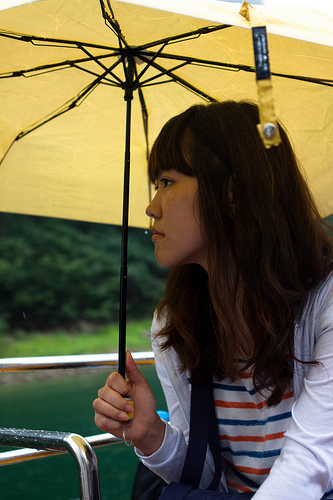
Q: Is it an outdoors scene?
A: Yes, it is outdoors.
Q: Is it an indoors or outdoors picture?
A: It is outdoors.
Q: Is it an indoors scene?
A: No, it is outdoors.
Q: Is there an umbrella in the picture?
A: Yes, there is an umbrella.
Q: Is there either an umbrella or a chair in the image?
A: Yes, there is an umbrella.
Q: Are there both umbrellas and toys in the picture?
A: No, there is an umbrella but no toys.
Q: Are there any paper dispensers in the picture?
A: No, there are no paper dispensers.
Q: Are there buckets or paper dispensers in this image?
A: No, there are no paper dispensers or buckets.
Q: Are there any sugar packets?
A: No, there are no sugar packets.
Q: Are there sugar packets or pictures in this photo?
A: No, there are no sugar packets or pictures.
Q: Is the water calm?
A: Yes, the water is calm.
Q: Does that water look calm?
A: Yes, the water is calm.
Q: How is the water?
A: The water is calm.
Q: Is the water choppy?
A: No, the water is calm.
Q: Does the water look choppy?
A: No, the water is calm.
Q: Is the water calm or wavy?
A: The water is calm.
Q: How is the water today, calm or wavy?
A: The water is calm.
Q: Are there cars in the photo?
A: No, there are no cars.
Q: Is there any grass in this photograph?
A: Yes, there is grass.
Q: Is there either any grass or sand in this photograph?
A: Yes, there is grass.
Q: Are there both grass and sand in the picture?
A: No, there is grass but no sand.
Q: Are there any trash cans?
A: No, there are no trash cans.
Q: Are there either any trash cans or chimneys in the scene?
A: No, there are no trash cans or chimneys.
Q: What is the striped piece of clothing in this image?
A: The clothing item is a shirt.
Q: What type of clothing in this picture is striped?
A: The clothing is a shirt.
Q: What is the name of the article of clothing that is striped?
A: The clothing item is a shirt.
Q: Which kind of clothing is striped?
A: The clothing is a shirt.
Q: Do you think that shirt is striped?
A: Yes, the shirt is striped.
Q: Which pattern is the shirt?
A: The shirt is striped.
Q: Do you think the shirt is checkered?
A: No, the shirt is striped.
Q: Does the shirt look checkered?
A: No, the shirt is striped.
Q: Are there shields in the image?
A: No, there are no shields.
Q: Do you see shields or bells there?
A: No, there are no shields or bells.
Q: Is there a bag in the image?
A: Yes, there is a bag.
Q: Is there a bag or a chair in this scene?
A: Yes, there is a bag.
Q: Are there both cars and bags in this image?
A: No, there is a bag but no cars.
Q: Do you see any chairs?
A: No, there are no chairs.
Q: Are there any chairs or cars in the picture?
A: No, there are no chairs or cars.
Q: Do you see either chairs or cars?
A: No, there are no chairs or cars.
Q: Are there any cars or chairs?
A: No, there are no chairs or cars.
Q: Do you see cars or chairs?
A: No, there are no chairs or cars.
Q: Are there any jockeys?
A: No, there are no jockeys.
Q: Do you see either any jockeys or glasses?
A: No, there are no jockeys or glasses.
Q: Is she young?
A: Yes, the girl is young.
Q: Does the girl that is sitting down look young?
A: Yes, the girl is young.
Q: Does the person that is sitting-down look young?
A: Yes, the girl is young.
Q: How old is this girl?
A: The girl is young.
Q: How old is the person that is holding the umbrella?
A: The girl is young.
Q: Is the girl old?
A: No, the girl is young.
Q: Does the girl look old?
A: No, the girl is young.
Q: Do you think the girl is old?
A: No, the girl is young.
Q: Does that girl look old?
A: No, the girl is young.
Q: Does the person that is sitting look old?
A: No, the girl is young.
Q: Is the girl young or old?
A: The girl is young.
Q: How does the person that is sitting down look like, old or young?
A: The girl is young.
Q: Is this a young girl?
A: Yes, this is a young girl.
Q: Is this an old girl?
A: No, this is a young girl.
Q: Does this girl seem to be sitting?
A: Yes, the girl is sitting.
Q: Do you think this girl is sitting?
A: Yes, the girl is sitting.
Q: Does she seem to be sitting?
A: Yes, the girl is sitting.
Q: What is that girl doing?
A: The girl is sitting.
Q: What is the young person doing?
A: The girl is sitting.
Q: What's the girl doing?
A: The girl is sitting.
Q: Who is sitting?
A: The girl is sitting.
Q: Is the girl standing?
A: No, the girl is sitting.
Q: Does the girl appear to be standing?
A: No, the girl is sitting.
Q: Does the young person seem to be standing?
A: No, the girl is sitting.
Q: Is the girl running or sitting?
A: The girl is sitting.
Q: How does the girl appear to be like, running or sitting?
A: The girl is sitting.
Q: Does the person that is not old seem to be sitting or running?
A: The girl is sitting.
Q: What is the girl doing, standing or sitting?
A: The girl is sitting.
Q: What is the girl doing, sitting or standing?
A: The girl is sitting.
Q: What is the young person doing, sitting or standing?
A: The girl is sitting.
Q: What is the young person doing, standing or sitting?
A: The girl is sitting.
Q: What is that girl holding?
A: The girl is holding the umbrella.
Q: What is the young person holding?
A: The girl is holding the umbrella.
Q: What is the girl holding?
A: The girl is holding the umbrella.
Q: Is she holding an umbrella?
A: Yes, the girl is holding an umbrella.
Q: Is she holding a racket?
A: No, the girl is holding an umbrella.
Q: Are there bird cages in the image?
A: No, there are no bird cages.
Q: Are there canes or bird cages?
A: No, there are no bird cages or canes.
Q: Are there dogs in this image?
A: No, there are no dogs.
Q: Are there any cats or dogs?
A: No, there are no dogs or cats.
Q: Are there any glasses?
A: No, there are no glasses.